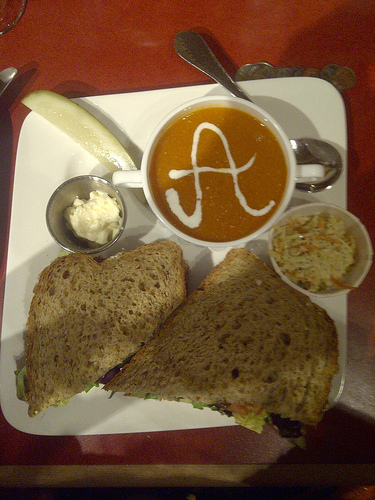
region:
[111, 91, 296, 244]
Cup of soup with letter A written in sour cream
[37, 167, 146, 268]
A serving of butter in a stainless steel container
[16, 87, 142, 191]
A slice of a pickle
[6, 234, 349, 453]
Two halves of a sandwich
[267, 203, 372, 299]
A bowl of cole slaw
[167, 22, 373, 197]
A spoon behind a cup of soup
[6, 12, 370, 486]
Lunch of soup and a sandwich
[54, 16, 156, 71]
A reddish countertop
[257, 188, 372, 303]
A bowl of relish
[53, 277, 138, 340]
Part of a slice of brown bread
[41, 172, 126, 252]
Butter in a silver bowl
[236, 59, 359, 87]
A row of coins on table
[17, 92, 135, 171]
A slice of pickle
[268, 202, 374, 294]
Coleslaw in a white paper cup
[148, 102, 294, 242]
The letter A in soup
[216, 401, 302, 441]
Lettuce inside sandwich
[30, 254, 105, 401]
Slice of wheat bread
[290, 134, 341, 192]
silver spoon on plate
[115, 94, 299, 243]
A white mug with soup in it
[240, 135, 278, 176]
Orange tomato soup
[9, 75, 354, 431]
a plate with food on it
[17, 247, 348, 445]
a sandwich is on the plate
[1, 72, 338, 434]
the plate is white in color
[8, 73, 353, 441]
the plate is a square like shape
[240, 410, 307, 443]
the sandwich has lettuce in it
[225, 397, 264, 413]
tomatoes are in the sandwich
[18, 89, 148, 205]
a pickle is on the plate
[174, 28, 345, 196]
a spoon is on the plate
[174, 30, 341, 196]
the spoon is silver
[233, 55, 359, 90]
coins are right beside the plate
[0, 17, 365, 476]
food in dinner plate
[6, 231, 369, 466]
sandwich on dinner plate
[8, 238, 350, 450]
sandwich bread is brown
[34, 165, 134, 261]
silver container on plate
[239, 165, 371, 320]
white container on plate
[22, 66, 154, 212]
pickle spear on plate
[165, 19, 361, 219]
spoon on corner of plate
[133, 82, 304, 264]
white bowl on plate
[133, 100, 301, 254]
orange soup in bowl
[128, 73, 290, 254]
white sauce on soup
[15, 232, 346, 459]
two sandwich halves with wheat bread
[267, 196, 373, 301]
small circular bowl of coleslaw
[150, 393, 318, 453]
lettuce and tomato inside of sandwich half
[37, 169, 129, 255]
small circular metal bowl of mayonnaise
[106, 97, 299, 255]
white coffee cup of brown beverage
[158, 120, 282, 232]
white liquid design on top of brown beverage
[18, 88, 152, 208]
long slice of pickle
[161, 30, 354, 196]
metal spoon next to coffee cup on white plate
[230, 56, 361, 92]
loose change at edge of white plate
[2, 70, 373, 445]
white square porcelain plate